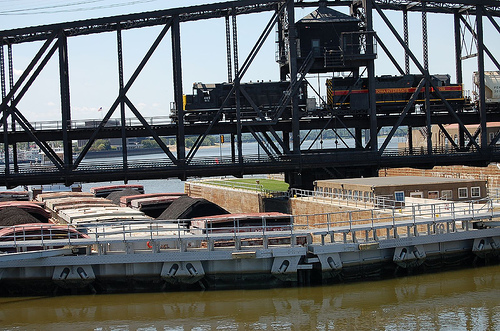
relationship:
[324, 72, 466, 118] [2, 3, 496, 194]
engines on bridge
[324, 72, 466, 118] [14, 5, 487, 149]
engines traveling on bridge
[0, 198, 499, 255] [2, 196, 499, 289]
railing on dock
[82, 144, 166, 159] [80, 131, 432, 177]
ship on water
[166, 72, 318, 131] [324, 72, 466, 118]
engine of engines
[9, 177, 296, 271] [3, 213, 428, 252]
cargo behind gate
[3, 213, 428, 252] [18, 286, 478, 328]
gate in river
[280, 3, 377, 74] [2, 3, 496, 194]
house in bridge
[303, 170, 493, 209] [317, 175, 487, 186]
building has roof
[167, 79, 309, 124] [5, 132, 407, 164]
engine above water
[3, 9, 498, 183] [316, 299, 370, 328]
sky reflecting water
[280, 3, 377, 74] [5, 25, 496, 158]
house on bridge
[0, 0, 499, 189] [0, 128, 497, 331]
bridge across river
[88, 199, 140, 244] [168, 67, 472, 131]
car behind engines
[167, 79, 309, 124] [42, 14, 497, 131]
engine on bridge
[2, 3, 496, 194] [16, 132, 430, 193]
bridge over water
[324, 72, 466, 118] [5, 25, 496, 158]
engines over bridge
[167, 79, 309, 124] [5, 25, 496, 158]
engine over bridge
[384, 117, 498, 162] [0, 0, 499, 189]
building near bridge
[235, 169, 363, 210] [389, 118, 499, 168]
rails in front of building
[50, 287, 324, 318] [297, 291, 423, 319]
reflections on water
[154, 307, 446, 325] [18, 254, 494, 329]
reflection in water